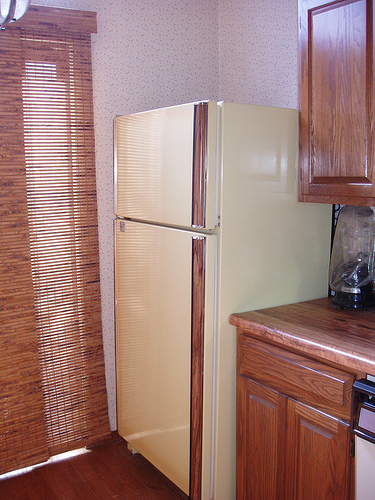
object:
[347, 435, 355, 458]
hinge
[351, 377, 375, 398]
top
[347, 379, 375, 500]
dishwasher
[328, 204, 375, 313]
blender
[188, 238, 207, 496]
wood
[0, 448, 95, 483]
light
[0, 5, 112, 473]
blinds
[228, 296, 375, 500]
cabinet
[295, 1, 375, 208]
cabinet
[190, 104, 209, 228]
wood trim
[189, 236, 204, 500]
wood trim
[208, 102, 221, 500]
strip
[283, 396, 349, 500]
door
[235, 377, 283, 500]
door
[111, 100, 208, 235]
door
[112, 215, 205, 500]
door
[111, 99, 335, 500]
fridge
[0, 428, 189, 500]
plank floor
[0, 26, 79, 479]
window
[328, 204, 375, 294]
bag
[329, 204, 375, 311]
blending sitting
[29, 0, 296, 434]
wallpaper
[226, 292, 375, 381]
counter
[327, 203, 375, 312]
appliance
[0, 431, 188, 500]
floors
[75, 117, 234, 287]
refrigerator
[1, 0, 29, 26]
light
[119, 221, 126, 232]
sticker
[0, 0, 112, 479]
curtain